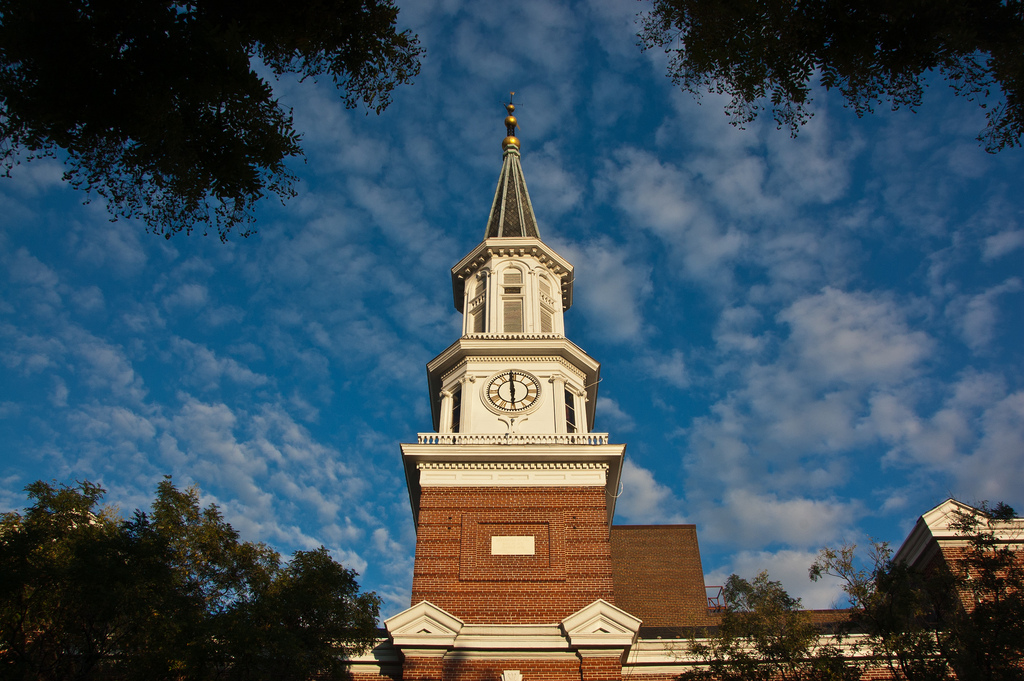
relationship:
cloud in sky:
[65, 170, 415, 389] [88, 209, 339, 447]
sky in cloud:
[0, 0, 1024, 633] [129, 157, 534, 372]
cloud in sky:
[125, 118, 560, 397] [43, 73, 353, 298]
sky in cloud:
[101, 90, 419, 298] [114, 85, 555, 269]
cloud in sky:
[62, 178, 393, 460] [129, 187, 348, 378]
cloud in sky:
[123, 77, 463, 216] [237, 73, 836, 352]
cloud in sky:
[203, 142, 649, 417] [93, 105, 835, 471]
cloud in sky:
[132, 114, 815, 419] [199, 58, 940, 400]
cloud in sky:
[631, 252, 822, 467] [553, 157, 957, 400]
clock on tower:
[369, 142, 624, 531] [399, 122, 661, 647]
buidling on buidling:
[381, 106, 644, 681] [315, 70, 733, 635]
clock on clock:
[479, 367, 547, 418] [399, 114, 672, 626]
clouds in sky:
[24, 114, 606, 385] [93, 51, 906, 419]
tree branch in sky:
[0, 3, 372, 248] [110, 181, 376, 410]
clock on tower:
[479, 367, 547, 418] [348, 88, 690, 611]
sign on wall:
[490, 534, 536, 556] [376, 135, 608, 663]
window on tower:
[393, 269, 614, 514] [317, 120, 667, 676]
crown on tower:
[423, 202, 650, 581] [347, 90, 665, 641]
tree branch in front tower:
[0, 3, 417, 248] [369, 83, 644, 665]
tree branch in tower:
[0, 3, 417, 248] [360, 129, 657, 641]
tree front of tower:
[682, 578, 842, 671] [427, 105, 624, 594]